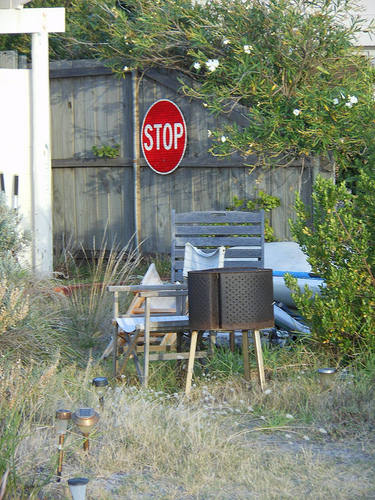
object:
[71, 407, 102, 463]
solar light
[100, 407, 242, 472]
grass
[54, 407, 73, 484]
solar light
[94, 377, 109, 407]
solar light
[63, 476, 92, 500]
solar light